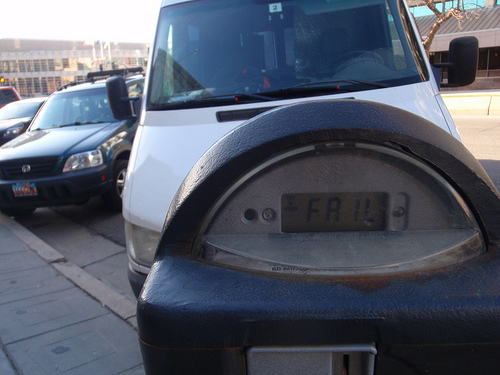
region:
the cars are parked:
[15, 24, 420, 292]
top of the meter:
[161, 130, 481, 300]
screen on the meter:
[287, 187, 417, 236]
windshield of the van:
[124, 0, 414, 92]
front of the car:
[6, 144, 101, 176]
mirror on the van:
[107, 82, 142, 129]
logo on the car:
[17, 156, 34, 173]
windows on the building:
[3, 53, 75, 86]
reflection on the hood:
[39, 129, 74, 146]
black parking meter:
[163, 111, 488, 370]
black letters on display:
[294, 184, 388, 240]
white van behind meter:
[135, 9, 452, 241]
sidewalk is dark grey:
[19, 265, 120, 374]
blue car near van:
[5, 55, 155, 210]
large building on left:
[2, 40, 124, 95]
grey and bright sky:
[1, 6, 136, 43]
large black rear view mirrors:
[442, 38, 487, 98]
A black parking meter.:
[135, 98, 498, 373]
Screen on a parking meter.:
[279, 189, 388, 230]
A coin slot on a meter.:
[247, 344, 377, 373]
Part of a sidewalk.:
[2, 217, 144, 371]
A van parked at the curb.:
[118, 0, 462, 299]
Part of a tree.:
[410, 0, 491, 59]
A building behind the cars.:
[2, 38, 149, 100]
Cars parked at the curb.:
[3, 3, 480, 303]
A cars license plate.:
[11, 180, 38, 199]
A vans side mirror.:
[427, 34, 478, 87]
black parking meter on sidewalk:
[149, 95, 494, 368]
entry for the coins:
[332, 354, 363, 373]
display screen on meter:
[283, 190, 387, 231]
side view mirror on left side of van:
[433, 37, 488, 86]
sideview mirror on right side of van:
[100, 73, 131, 123]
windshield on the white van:
[149, 0, 428, 101]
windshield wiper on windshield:
[189, 88, 277, 105]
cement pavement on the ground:
[0, 244, 131, 372]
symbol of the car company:
[16, 162, 33, 178]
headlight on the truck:
[63, 150, 102, 174]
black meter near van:
[179, 115, 462, 335]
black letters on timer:
[295, 185, 378, 225]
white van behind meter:
[162, 4, 464, 244]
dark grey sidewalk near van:
[14, 254, 64, 374]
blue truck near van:
[4, 64, 144, 206]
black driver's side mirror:
[422, 30, 479, 97]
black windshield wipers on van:
[189, 74, 334, 97]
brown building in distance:
[3, 39, 120, 97]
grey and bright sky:
[1, 6, 143, 29]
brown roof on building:
[415, 11, 492, 33]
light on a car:
[65, 135, 111, 176]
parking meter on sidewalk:
[175, 98, 488, 264]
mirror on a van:
[431, 37, 481, 83]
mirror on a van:
[94, 70, 141, 120]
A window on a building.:
[18, 59, 27, 73]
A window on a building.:
[48, 60, 55, 72]